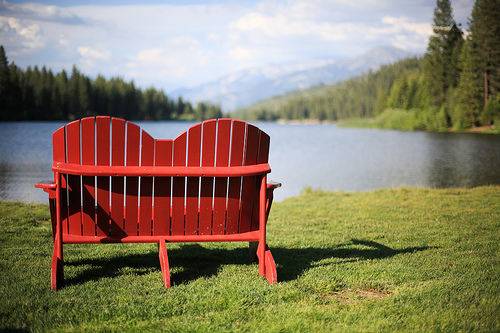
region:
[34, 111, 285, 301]
Red bench sitting on grass near lake.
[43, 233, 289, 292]
Three legs to support bench.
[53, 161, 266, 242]
Back guard to support back slats.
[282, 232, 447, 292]
Shadow of bench on grass.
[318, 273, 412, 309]
Bare spot on grass.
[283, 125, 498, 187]
A lake beyond grass and bench.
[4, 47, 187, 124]
Pine tress growing along edge of lake.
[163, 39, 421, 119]
Mountain range in background beyond pine trees.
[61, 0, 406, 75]
A cloudy overcast sky.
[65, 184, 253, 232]
Red slats for back of bench.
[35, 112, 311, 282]
red two person bench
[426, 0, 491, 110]
evergreen trees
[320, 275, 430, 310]
patch of dirt in the grass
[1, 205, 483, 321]
lush green grass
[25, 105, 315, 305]
red plastic bench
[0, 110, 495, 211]
smooth, waveless water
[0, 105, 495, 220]
still, smooth, calm lake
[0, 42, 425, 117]
blurry treeline behind a lake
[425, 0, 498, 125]
two tall trees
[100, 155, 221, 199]
screw holes in a bench's back board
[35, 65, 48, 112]
a tree in a distance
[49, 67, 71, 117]
a tree in a distance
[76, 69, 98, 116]
a tree in a distance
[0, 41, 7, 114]
a tree in a distance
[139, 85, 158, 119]
a tree in a distance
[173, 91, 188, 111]
a tree in a distance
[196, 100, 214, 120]
a tree in a distance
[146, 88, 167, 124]
a tree in a distance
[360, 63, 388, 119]
a tree in a distance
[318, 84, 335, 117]
a tree in a distance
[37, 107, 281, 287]
A red wooden bench at the water's edge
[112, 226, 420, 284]
The shadow of a bench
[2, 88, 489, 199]
A beautiful placid lake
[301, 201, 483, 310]
Grass at the side of a lake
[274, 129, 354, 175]
Sun shining on the surface of a lake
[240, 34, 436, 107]
Mountains in the distance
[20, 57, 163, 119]
Pines growing alongside a lake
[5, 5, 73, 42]
Puffy white clouds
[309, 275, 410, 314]
A dirt patch in the grass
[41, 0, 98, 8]
Blue sky above the crowds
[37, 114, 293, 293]
a bench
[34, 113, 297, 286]
a wooden bench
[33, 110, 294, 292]
the bench is made of wood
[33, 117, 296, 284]
the bench is red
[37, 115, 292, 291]
the wooden bench is red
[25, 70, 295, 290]
the bench is on the grass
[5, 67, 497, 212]
a lake is in front of the bench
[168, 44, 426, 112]
a mountain is on the far side of the lake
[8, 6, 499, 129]
trees are on the other shoreline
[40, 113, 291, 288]
the red bench is for sitting by the water